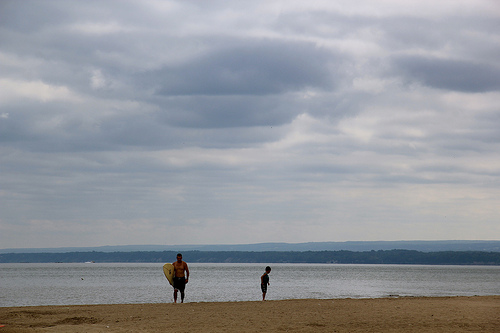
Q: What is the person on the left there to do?
A: Surf.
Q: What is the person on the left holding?
A: Surfboard.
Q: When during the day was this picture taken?
A: Daytime.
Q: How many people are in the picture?
A: Two.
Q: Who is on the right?
A: Child.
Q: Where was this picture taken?
A: Beach.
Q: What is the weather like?
A: Cloudy.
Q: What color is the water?
A: Gray.